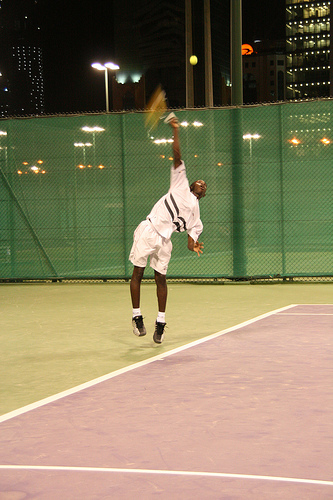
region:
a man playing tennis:
[57, 89, 297, 384]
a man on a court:
[59, 81, 265, 360]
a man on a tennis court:
[74, 86, 322, 434]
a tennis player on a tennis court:
[103, 46, 327, 413]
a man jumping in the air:
[95, 87, 247, 331]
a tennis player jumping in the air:
[76, 82, 311, 396]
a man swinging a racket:
[102, 70, 268, 381]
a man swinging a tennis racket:
[55, 98, 251, 379]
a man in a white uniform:
[46, 95, 250, 360]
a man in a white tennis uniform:
[75, 32, 237, 362]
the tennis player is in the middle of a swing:
[124, 91, 212, 348]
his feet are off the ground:
[126, 308, 171, 352]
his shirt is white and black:
[149, 154, 203, 247]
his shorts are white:
[123, 214, 176, 278]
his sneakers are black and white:
[130, 315, 147, 341]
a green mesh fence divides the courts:
[4, 120, 331, 278]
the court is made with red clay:
[0, 302, 327, 497]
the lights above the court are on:
[83, 58, 124, 107]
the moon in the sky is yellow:
[188, 53, 200, 67]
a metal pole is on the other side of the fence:
[226, 3, 243, 105]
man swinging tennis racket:
[127, 85, 206, 344]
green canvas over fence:
[0, 99, 330, 280]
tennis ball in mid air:
[186, 52, 201, 69]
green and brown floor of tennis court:
[1, 276, 331, 497]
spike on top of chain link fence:
[3, 95, 330, 119]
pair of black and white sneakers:
[129, 313, 166, 344]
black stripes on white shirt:
[162, 189, 186, 238]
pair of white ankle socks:
[128, 305, 167, 322]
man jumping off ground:
[126, 116, 210, 343]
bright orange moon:
[238, 42, 253, 53]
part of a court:
[206, 449, 223, 471]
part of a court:
[190, 421, 210, 452]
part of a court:
[183, 428, 200, 450]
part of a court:
[222, 401, 247, 440]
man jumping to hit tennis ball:
[124, 78, 204, 347]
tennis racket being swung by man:
[144, 91, 183, 124]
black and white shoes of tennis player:
[129, 309, 168, 342]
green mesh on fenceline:
[9, 117, 332, 274]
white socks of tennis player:
[130, 300, 168, 320]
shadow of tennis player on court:
[34, 315, 196, 359]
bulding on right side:
[281, 9, 331, 100]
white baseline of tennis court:
[12, 296, 305, 430]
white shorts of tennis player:
[128, 219, 172, 268]